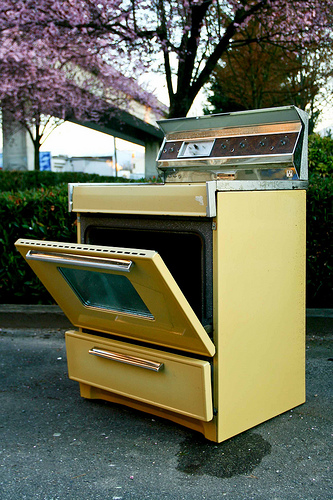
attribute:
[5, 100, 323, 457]
stove — old, yellow, tan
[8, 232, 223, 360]
door — open, half opened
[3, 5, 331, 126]
flowers — bright purple, purple, colorful, pink, background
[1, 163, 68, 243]
bushes — pruned, dark green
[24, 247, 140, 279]
handle — silver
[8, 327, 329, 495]
ground — speckled grey, grey, black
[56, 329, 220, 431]
drawer — yellow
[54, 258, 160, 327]
window — glass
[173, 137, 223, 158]
clock — damaged